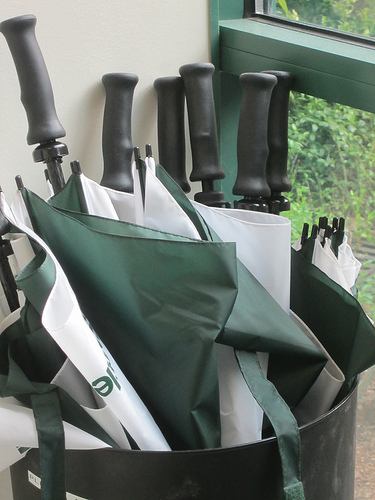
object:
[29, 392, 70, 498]
green strap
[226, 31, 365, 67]
nike logo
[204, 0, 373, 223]
window frame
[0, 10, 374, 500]
umbrella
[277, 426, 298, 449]
part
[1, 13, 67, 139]
handle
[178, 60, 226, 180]
handle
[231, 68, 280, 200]
handle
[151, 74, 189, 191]
handle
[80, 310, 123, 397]
writing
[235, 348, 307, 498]
ribbon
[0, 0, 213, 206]
wall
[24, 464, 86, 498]
sticker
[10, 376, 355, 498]
barrel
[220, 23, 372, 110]
sill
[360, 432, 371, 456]
ground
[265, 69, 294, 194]
handles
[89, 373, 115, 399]
e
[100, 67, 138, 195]
handle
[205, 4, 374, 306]
window